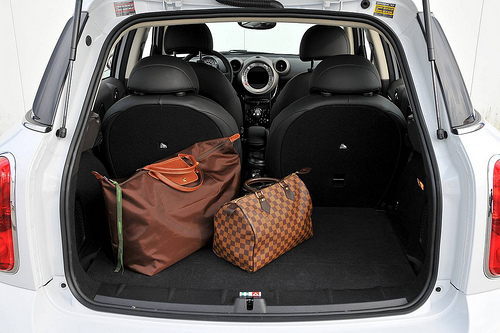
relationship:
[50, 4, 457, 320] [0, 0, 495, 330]
trunk of a car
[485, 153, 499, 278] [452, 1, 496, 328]
tail light on right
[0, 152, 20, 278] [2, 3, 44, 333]
tail light on left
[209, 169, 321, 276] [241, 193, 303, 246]
bag has desigs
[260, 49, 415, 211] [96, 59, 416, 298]
seat on back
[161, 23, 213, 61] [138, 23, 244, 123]
head rest of front seats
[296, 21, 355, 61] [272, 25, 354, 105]
head rest of passenger seat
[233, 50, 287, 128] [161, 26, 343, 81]
console between front seats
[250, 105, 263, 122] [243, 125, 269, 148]
buttons in front gear shift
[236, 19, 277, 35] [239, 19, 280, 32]
mirror for rear view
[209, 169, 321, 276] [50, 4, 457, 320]
bag in trunk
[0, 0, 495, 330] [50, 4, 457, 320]
car has trunk open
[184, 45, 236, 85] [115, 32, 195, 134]
steering wheel on left side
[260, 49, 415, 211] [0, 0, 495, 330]
seat in back car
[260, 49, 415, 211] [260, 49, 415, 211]
seat on seat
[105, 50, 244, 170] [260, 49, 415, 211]
seat on seat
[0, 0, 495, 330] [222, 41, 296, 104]
vehicle front dashboard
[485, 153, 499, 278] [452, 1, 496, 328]
light on right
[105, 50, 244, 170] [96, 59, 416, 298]
seat on back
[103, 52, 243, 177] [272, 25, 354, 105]
back of seat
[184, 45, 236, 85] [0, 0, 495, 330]
steering wheel of car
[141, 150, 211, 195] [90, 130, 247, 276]
handles of purse